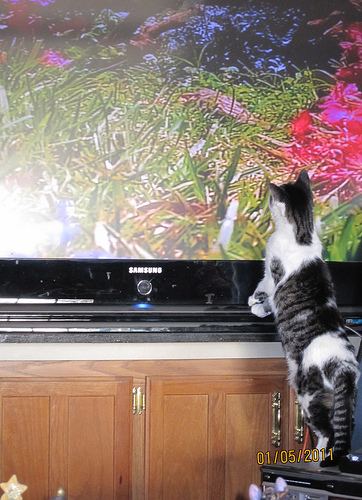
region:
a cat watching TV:
[249, 169, 358, 468]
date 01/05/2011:
[252, 445, 336, 464]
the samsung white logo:
[126, 265, 163, 273]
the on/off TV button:
[135, 277, 150, 294]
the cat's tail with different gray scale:
[328, 364, 356, 445]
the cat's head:
[262, 169, 312, 229]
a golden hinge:
[131, 385, 144, 412]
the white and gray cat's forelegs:
[247, 258, 275, 319]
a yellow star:
[0, 471, 27, 496]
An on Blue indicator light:
[135, 302, 153, 309]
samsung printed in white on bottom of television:
[122, 264, 165, 278]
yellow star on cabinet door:
[0, 470, 29, 498]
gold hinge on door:
[131, 384, 146, 413]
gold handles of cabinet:
[262, 386, 307, 445]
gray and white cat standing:
[247, 170, 356, 463]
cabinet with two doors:
[2, 362, 359, 499]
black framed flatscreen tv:
[2, 2, 361, 309]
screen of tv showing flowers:
[2, 3, 361, 242]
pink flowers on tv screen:
[297, 21, 361, 199]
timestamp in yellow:
[251, 445, 337, 465]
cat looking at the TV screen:
[160, 150, 343, 322]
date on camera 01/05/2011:
[253, 443, 336, 468]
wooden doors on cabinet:
[145, 369, 297, 498]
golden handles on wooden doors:
[264, 390, 289, 449]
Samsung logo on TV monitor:
[123, 260, 167, 277]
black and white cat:
[249, 174, 360, 416]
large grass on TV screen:
[24, 56, 224, 224]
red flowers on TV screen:
[302, 78, 360, 167]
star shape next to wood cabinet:
[1, 470, 37, 498]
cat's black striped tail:
[329, 363, 360, 467]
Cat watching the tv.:
[255, 160, 361, 405]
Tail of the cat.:
[280, 336, 361, 460]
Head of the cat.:
[259, 163, 315, 226]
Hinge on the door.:
[129, 383, 161, 424]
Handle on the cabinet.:
[268, 385, 301, 453]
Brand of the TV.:
[107, 250, 183, 286]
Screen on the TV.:
[6, 118, 275, 267]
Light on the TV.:
[127, 294, 173, 319]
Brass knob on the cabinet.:
[264, 386, 292, 465]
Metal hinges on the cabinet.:
[117, 368, 187, 449]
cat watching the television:
[231, 153, 361, 464]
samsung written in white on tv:
[121, 262, 164, 279]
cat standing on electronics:
[250, 174, 360, 499]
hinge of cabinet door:
[129, 385, 144, 414]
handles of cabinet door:
[261, 388, 303, 445]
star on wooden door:
[0, 473, 28, 496]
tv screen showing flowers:
[0, 1, 358, 257]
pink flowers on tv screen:
[9, 6, 360, 188]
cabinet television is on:
[4, 360, 360, 498]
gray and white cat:
[242, 174, 356, 463]